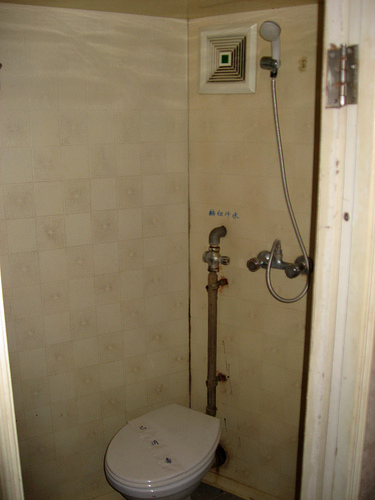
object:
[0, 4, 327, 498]
shower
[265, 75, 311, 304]
hose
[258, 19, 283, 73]
showerhead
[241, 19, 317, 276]
shower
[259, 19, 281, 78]
shower head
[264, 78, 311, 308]
piping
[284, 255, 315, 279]
valve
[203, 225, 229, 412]
waterpipe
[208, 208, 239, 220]
writing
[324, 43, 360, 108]
hinge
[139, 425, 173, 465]
sign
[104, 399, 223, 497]
toilet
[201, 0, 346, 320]
head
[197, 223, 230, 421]
pipe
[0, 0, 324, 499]
wall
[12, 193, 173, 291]
tile design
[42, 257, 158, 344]
tiles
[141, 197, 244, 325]
pipe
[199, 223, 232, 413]
pipe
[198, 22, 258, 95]
vent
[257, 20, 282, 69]
shower head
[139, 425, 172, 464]
writing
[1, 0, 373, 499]
bathroom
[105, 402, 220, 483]
lid